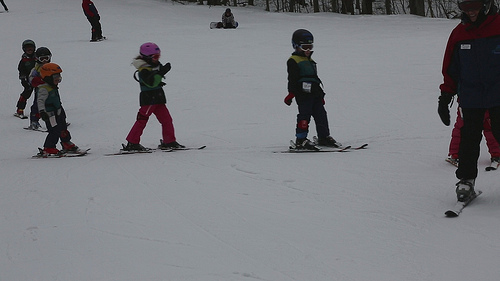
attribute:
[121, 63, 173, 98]
coat — red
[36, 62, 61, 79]
helmet — orange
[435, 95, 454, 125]
glove — black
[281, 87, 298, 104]
glove — black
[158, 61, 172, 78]
glove — black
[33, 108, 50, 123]
glove — black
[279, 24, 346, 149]
kid — skiing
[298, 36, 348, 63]
goggles — silver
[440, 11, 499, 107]
coat — dark blue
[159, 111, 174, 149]
pants — dark pink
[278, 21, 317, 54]
helmet — blue